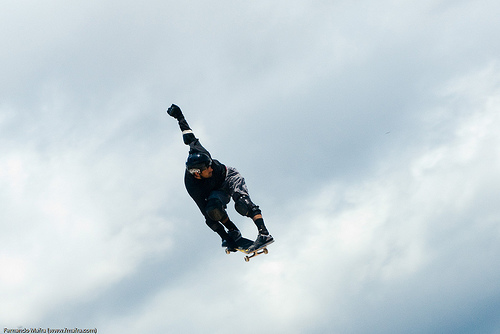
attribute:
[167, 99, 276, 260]
skateboarder — in air, jumping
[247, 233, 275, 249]
shoe — black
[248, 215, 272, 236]
sock — black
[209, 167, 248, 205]
pants — white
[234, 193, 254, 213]
knee pad — covered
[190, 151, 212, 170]
helmet — black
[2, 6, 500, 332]
sky — cloudy, gray, blue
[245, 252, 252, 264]
wheel — light colored, small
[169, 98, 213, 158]
arm — raised, extended, stretched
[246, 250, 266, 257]
arm — truck